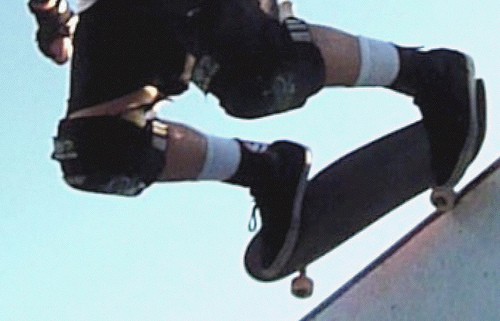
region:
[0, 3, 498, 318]
skate boarder on top of half pipe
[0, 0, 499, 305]
skater wearing protective knee pads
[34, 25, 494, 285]
skater wearing black shoes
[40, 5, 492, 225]
skater wearing white socks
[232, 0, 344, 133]
velcro on knee pads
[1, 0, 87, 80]
skater wearing protective gloves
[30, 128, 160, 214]
brand name on knee pad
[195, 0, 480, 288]
black braces on ankles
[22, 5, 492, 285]
skater with knees bent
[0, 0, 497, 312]
skater wearing black shorts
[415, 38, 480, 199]
black sneaker with a white sole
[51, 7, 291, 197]
pair of black kneepads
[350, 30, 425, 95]
white sock under an ankle band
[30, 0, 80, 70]
black open handed gloves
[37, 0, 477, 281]
skateboarder wearing black shorts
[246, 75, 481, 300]
black skateboard with white wheels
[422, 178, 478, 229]
wheel touching the side of the ramp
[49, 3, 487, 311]
skateboarder perched on a skate ramp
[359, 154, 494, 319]
cement skate ramp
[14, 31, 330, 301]
light aqua sky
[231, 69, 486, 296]
a black skate board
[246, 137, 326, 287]
a black gym shoe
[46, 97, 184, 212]
one black knee pad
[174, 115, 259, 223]
white cotton high top sox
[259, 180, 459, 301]
wheels on a skate board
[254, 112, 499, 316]
skate board rolling on a wall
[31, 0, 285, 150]
black cow denum shorts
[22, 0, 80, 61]
a black strapped wrist band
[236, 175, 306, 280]
black shoe string on black shoes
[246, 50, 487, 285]
feet on a black skate board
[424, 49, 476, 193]
a black and white shoe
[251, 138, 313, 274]
a black and white shoe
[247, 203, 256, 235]
a black shoelace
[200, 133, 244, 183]
the top of a white sock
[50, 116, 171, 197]
a black knee pad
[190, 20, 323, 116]
a black knee pad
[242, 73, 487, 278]
a black skateboard being ridden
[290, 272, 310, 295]
a yellow skateboard wheel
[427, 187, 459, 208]
a yellow skateboard wheel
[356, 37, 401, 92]
the top of a white sock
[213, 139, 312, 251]
Black shoes on a skateboard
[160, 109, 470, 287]
person on a skateboard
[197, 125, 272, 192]
person wearing white socks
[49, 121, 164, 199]
person wearing knee boards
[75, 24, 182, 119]
person wearing black shorts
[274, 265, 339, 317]
Yellow wheels on a skateboard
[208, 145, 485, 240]
Man on a skateboard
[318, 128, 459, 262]
Man on a skateboard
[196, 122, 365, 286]
Man on a skateboard